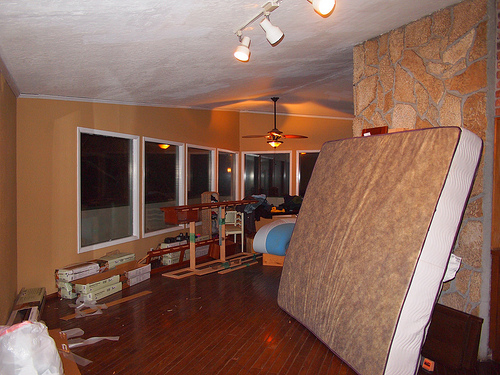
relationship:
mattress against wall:
[277, 128, 485, 371] [353, 0, 499, 368]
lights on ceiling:
[233, 3, 337, 66] [0, 2, 473, 119]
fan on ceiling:
[240, 94, 313, 148] [0, 2, 473, 119]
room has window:
[1, 2, 497, 374] [77, 126, 137, 250]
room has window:
[1, 2, 497, 374] [145, 138, 186, 236]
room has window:
[1, 2, 497, 374] [186, 142, 211, 206]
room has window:
[1, 2, 497, 374] [217, 149, 238, 204]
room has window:
[1, 2, 497, 374] [246, 152, 291, 198]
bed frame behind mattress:
[422, 303, 483, 374] [277, 128, 485, 371]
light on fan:
[267, 141, 283, 149] [240, 94, 313, 148]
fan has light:
[240, 94, 313, 148] [267, 141, 283, 149]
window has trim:
[77, 126, 137, 250] [77, 128, 138, 251]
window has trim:
[145, 138, 186, 236] [140, 136, 185, 237]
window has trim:
[186, 142, 211, 206] [187, 144, 214, 202]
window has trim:
[217, 149, 238, 204] [219, 148, 238, 198]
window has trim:
[246, 152, 291, 198] [243, 150, 291, 202]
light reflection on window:
[157, 140, 171, 150] [145, 138, 186, 236]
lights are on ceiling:
[233, 3, 337, 66] [0, 2, 473, 119]